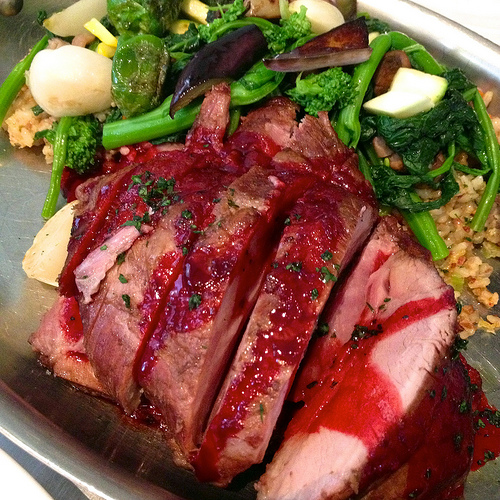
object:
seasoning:
[57, 133, 500, 500]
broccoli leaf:
[359, 155, 456, 216]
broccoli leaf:
[378, 67, 488, 157]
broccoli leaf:
[109, 36, 170, 121]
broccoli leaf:
[110, 0, 158, 40]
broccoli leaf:
[246, 72, 286, 103]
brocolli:
[358, 85, 490, 209]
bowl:
[0, 1, 497, 500]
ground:
[245, 60, 287, 84]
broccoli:
[285, 65, 360, 116]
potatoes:
[29, 45, 115, 117]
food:
[0, 0, 500, 500]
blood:
[290, 212, 308, 310]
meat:
[27, 82, 479, 497]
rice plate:
[401, 135, 497, 329]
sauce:
[171, 225, 243, 343]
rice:
[425, 177, 500, 340]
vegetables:
[1, 1, 500, 260]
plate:
[0, 0, 500, 500]